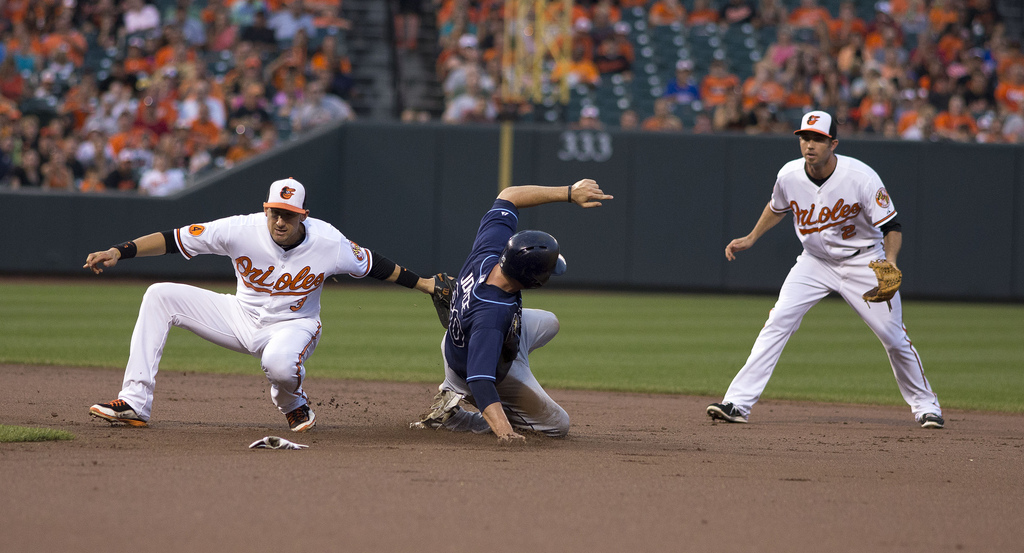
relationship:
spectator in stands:
[699, 61, 739, 97] [4, 0, 1022, 200]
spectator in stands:
[445, 65, 493, 95] [4, 0, 1022, 200]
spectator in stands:
[77, 133, 115, 157] [4, 0, 1022, 200]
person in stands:
[139, 153, 186, 198] [4, 0, 1022, 200]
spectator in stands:
[935, 90, 975, 130] [4, 0, 1022, 200]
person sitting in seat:
[104, 147, 146, 193] [665, 19, 694, 39]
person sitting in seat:
[142, 147, 188, 202] [639, 41, 663, 65]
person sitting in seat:
[288, 80, 365, 120] [633, 67, 666, 87]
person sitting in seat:
[80, 87, 125, 130] [731, 38, 767, 68]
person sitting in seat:
[663, 55, 706, 97] [611, 101, 650, 118]